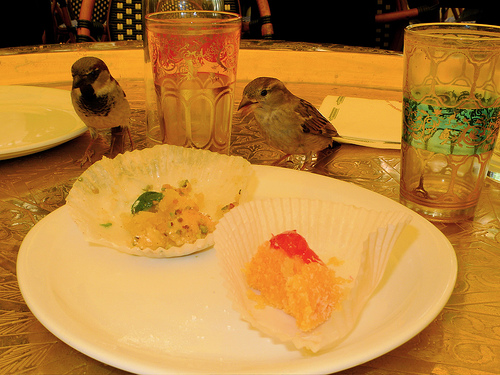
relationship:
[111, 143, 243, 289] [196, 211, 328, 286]
pastry over cherry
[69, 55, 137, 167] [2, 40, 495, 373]
bird on table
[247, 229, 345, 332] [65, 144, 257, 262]
food in paper cup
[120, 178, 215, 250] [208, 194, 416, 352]
pastry in paper cup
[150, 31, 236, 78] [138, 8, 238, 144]
design on glass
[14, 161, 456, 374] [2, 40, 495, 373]
plate on table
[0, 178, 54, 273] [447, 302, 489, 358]
gold design on table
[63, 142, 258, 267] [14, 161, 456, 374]
food paper on plate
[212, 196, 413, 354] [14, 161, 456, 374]
food paper on plate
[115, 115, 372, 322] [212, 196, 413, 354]
food on food paper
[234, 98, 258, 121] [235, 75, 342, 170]
beak of bird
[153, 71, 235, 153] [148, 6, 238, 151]
water in glass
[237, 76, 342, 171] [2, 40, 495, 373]
birds on table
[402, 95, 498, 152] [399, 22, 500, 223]
green accents on glass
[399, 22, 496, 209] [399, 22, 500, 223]
gold accents on glass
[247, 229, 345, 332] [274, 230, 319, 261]
food with cherry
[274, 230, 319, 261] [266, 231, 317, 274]
cherry on top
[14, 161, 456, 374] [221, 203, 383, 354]
plate with desert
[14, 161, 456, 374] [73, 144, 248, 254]
plate with desert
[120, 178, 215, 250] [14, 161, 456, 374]
pastry on a plate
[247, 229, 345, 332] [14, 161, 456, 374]
food on a plate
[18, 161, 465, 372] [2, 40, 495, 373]
plate sitting on table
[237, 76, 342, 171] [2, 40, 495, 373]
birds dining on table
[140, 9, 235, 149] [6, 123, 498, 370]
water on table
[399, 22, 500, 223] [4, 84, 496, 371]
glass on table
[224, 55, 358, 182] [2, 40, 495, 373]
birds on table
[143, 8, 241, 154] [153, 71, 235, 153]
glass half filled with water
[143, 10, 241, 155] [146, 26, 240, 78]
glass of water with design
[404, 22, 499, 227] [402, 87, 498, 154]
glass of water with green accents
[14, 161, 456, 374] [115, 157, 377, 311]
plate with food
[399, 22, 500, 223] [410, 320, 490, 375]
glass sitting on table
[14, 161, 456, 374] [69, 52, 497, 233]
plate on table